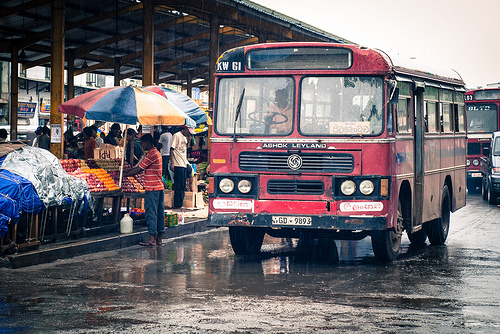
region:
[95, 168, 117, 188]
Orange fresh oranges in the market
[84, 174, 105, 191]
pink fresh apples in the market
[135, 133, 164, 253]
A man sellinh fruits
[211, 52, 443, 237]
A big red bus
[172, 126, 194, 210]
A man standing in the market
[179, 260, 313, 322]
floating water in the market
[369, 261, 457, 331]
floating water on the road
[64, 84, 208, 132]
A red yellow and blue big umbrells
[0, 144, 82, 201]
A coveres market stall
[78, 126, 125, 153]
people in the market place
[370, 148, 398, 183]
the bus is red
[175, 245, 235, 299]
the street has water on it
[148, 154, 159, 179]
the shirt is stripped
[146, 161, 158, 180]
the shirt is orange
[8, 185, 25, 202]
the tarp is blue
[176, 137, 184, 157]
the shirt is white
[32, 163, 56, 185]
the tarp is gray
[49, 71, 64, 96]
the pole is yellow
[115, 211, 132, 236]
the jug is on the sidewalk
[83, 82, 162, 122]
the umbrella is multi color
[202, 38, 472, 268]
red older style bus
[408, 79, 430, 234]
loading and unloading door of bus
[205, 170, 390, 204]
headlights of old red bus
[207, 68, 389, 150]
windshield of old style bus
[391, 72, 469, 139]
passenger windows on old style bus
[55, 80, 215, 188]
multiple colored umbrellas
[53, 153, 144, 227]
fruit stand with several types of food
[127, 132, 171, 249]
man wearing striped polo style shirt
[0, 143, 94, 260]
blue and silver tarps over fruit on stands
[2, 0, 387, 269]
open outdoor market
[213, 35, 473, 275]
a red bus parked on the side of the road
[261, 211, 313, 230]
white license plate of the bus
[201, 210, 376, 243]
black metal bumper of the bus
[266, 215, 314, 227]
black lettering on a white license plate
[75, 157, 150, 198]
several stacked fruits on a table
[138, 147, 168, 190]
a man wearing an orange and white striped shirt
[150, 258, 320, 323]
black asphalt surface of the road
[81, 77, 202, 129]
colorful umbrellas over the fruit stand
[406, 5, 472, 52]
grey cloudy skies over the scene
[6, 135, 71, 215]
blue and grey tarps covering a table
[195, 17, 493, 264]
bus has multiple colors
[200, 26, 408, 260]
front of bus is red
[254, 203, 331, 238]
bus license plate is white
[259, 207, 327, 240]
licence plate has black writing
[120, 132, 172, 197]
man wearing striped shirt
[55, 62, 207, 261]
man standing under umbrella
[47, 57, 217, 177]
umbrella has multiple colors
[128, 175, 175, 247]
man wearing blue pants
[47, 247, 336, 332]
street is wet from rain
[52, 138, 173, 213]
food stacked on table